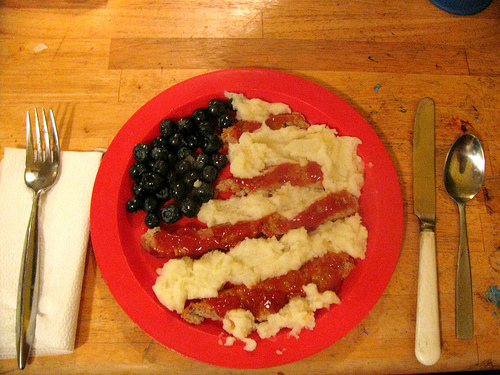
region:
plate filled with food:
[97, 54, 415, 362]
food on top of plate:
[120, 73, 371, 347]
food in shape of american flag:
[117, 89, 348, 356]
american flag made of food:
[97, 89, 358, 356]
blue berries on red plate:
[115, 88, 237, 238]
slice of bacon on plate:
[177, 251, 357, 330]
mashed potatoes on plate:
[172, 236, 338, 285]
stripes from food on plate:
[177, 117, 357, 309]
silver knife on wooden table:
[404, 79, 454, 374]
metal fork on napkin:
[3, 100, 68, 373]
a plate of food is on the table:
[104, 63, 401, 365]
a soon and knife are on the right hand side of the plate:
[397, 77, 489, 370]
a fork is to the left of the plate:
[6, 93, 68, 367]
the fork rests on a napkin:
[8, 98, 80, 366]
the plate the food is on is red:
[113, 70, 397, 371]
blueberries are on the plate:
[139, 100, 234, 216]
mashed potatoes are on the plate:
[244, 98, 336, 337]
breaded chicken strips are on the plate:
[195, 250, 355, 308]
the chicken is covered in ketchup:
[191, 246, 361, 331]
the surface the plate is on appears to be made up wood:
[101, 12, 397, 99]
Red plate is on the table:
[86, 62, 402, 371]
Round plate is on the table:
[87, 62, 407, 371]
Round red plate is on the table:
[85, 64, 409, 371]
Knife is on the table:
[405, 90, 446, 367]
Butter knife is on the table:
[405, 91, 450, 371]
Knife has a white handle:
[413, 227, 441, 367]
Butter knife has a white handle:
[414, 220, 443, 369]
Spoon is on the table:
[443, 130, 490, 345]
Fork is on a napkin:
[14, 105, 66, 368]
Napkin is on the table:
[2, 143, 107, 367]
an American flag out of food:
[114, 87, 371, 343]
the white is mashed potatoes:
[157, 86, 371, 357]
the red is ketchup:
[142, 87, 360, 323]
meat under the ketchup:
[154, 69, 359, 323]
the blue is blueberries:
[124, 92, 231, 230]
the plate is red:
[81, 59, 420, 371]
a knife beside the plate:
[411, 86, 436, 368]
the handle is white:
[407, 221, 452, 373]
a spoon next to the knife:
[439, 127, 485, 342]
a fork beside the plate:
[5, 101, 77, 371]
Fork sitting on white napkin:
[13, 105, 63, 372]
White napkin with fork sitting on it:
[1, 146, 102, 359]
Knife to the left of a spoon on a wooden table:
[412, 96, 442, 367]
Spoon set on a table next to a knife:
[441, 134, 484, 341]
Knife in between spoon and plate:
[411, 95, 441, 365]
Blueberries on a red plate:
[123, 96, 237, 228]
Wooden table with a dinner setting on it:
[3, 1, 497, 373]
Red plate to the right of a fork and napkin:
[91, 65, 404, 372]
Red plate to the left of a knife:
[90, 64, 405, 372]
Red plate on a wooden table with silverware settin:
[90, 64, 406, 368]